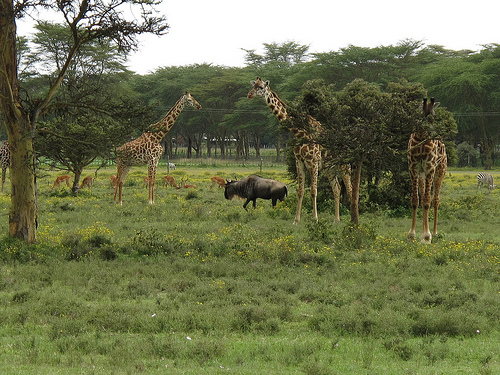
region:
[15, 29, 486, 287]
There are giraffes in the photo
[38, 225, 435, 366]
There is grass in the photo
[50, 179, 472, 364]
There is green grass in the photo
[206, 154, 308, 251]
There is a moose in the photo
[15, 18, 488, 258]
There are trees in the background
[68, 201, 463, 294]
There are flowers in the grass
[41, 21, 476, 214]
There are trees surrounding the animals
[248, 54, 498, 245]
The giraffe in the trees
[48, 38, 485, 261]
There are different types of animals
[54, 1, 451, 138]
The sky has no clouds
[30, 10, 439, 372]
Picture is taken outside.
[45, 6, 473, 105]
Picture is taken during the day.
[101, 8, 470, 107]
The sky is grey in color.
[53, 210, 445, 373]
The grass is green.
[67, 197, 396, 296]
Small yellow flowers dot the grass.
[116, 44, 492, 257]
There are 3 giraffes.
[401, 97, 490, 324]
One giraffe is eating branches and leaves.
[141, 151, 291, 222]
Gazelles are on the grass.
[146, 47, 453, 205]
The trees have lots of leaves.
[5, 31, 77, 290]
The tree trunk is green and brown in color.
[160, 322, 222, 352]
white paper on ground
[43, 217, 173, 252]
yellow flowers in the field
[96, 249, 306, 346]
green grass in the field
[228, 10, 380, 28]
clear skies overhead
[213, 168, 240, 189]
horns on animal's head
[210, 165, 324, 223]
small black animal running in the field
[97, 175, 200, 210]
brown feet on giraffe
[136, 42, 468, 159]
large selection of green trees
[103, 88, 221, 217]
large brown and tan giraffe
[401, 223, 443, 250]
small white feet on giraffe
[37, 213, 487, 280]
Flowers are bright yellow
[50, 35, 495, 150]
Trees are in the background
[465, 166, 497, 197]
A Zebra is in the background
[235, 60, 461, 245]
Two giraffes by each other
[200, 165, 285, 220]
Side view of a dark colored wildebeest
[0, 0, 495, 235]
Photo was taken in the daytime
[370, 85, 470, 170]
Giraffe has its head in a bush tree.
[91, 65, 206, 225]
Side view of a giraffe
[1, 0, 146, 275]
Tree is in the foreground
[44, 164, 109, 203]
Animals in the background are eating grass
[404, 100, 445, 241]
a giraffe eating leaves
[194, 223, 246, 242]
yellow flowers blooming in the field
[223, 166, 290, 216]
a wildebeest roaming the meadow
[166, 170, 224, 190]
several deer frolicking in the field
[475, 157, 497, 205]
a zebra munching on grass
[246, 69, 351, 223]
a giraffe peeking around a tree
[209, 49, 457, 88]
trees surrounding the field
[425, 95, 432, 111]
horns on top of a head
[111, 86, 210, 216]
a giraffe watching the wildebeest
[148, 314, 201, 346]
white flowers scattered in the grass